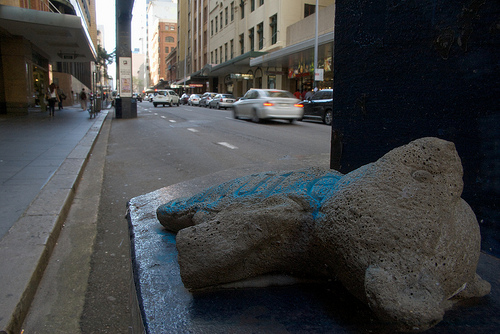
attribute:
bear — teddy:
[165, 123, 460, 258]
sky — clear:
[96, 7, 150, 52]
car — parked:
[293, 82, 333, 122]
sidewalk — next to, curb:
[0, 85, 110, 331]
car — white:
[200, 53, 327, 142]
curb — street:
[6, 102, 113, 320]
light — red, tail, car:
[260, 96, 276, 108]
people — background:
[21, 81, 116, 115]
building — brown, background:
[167, 2, 335, 109]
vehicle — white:
[151, 88, 181, 106]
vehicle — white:
[142, 91, 159, 102]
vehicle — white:
[230, 88, 303, 123]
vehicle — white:
[131, 93, 141, 102]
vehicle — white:
[299, 88, 332, 122]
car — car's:
[213, 66, 324, 141]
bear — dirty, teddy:
[157, 126, 483, 326]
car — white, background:
[230, 86, 303, 125]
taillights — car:
[261, 100, 303, 108]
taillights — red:
[262, 97, 307, 110]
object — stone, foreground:
[177, 133, 478, 319]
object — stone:
[152, 133, 486, 333]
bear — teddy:
[147, 137, 463, 304]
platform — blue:
[125, 163, 495, 331]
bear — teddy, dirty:
[169, 133, 478, 319]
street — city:
[151, 112, 229, 166]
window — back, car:
[263, 89, 295, 99]